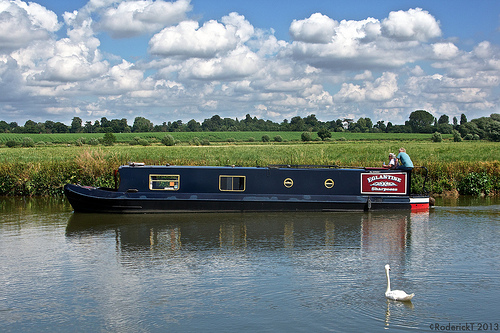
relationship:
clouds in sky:
[0, 1, 498, 125] [1, 2, 496, 112]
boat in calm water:
[58, 143, 466, 218] [0, 192, 500, 331]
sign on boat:
[359, 171, 408, 195] [60, 158, 427, 215]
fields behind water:
[8, 114, 464, 186] [3, 219, 361, 324]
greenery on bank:
[38, 127, 488, 187] [5, 148, 482, 204]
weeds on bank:
[20, 141, 460, 160] [5, 148, 482, 204]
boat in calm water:
[58, 160, 437, 214] [0, 192, 500, 331]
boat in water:
[58, 160, 437, 214] [63, 232, 379, 331]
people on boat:
[381, 146, 421, 171] [58, 160, 437, 214]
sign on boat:
[359, 171, 408, 197] [66, 152, 423, 200]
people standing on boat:
[378, 122, 424, 203] [66, 162, 481, 237]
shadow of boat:
[69, 216, 406, 252] [60, 153, 433, 206]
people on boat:
[394, 146, 416, 171] [58, 160, 437, 214]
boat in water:
[58, 160, 437, 214] [22, 258, 327, 322]